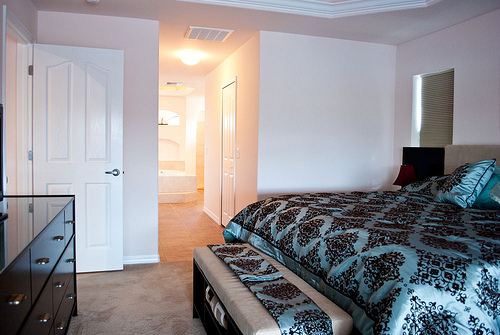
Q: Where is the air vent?
A: On the ceiling.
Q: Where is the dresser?
A: On the left.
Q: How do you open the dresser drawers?
A: With handles.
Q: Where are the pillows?
A: Near the headboard.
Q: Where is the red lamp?
A: Next to the bed.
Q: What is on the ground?
A: Carpet.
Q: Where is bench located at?
A: Foot of bed.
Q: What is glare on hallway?
A: Light.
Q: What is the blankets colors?
A: Blue and black.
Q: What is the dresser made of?
A: Wood.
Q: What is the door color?
A: White.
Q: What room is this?
A: Bedroom.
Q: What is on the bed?
A: Decorative sheets.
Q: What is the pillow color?
A: Black and blue.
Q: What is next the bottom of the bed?
A: Long ottoman with white cushion.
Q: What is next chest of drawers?
A: White door with metal handle.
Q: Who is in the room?
A: No one.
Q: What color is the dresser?
A: Brown.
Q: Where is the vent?
A: On the ceiling.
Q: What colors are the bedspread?
A: Blue and black.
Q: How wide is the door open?
A: All the way.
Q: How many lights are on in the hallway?
A: One.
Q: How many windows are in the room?
A: One.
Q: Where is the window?
A: By the bed.